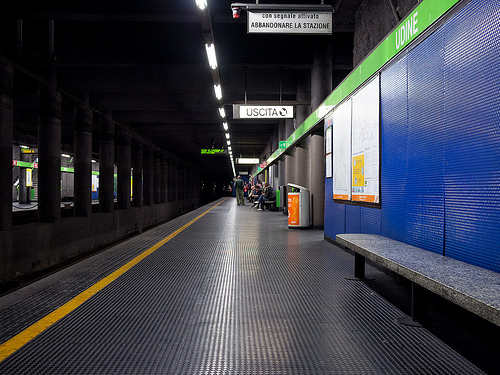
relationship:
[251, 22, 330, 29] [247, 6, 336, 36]
letter on sign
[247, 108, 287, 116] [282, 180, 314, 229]
black letter displayed on trashcan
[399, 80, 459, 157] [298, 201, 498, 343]
wall standing behind bench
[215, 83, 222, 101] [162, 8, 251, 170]
light on ceiling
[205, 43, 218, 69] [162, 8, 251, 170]
light on ceiling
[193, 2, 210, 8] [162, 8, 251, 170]
light on ceiling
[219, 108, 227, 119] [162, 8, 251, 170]
light on ceiling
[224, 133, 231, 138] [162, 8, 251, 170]
light on ceiling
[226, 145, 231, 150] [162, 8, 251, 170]
light on ceiling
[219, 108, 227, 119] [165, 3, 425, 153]
light on ceiling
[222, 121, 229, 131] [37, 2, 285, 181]
light on ceiling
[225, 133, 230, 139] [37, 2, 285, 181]
light on ceiling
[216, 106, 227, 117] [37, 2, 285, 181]
light on ceiling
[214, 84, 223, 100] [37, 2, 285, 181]
light on ceiling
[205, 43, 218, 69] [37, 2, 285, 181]
light on ceiling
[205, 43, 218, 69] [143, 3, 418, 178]
light on ceiling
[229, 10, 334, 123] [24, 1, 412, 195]
signs hanging from ceiling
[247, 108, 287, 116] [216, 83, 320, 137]
black letter on sign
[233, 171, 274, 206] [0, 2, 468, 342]
people in subway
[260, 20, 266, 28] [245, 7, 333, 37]
letter on sign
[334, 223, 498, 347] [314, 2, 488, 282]
bench in front of wall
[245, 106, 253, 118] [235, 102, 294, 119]
black letter printed on sign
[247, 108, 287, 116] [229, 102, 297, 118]
black letter printed on sign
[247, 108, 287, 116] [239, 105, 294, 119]
black letter printed on sign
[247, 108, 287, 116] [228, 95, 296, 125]
black letter on sign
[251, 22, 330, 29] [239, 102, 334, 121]
letter on sign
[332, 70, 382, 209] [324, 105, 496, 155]
map displayed on wall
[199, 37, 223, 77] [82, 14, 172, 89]
light on ceiling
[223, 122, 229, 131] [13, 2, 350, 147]
light on ceiling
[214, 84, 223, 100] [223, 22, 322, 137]
light on ceiling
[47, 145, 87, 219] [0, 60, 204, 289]
window of subway